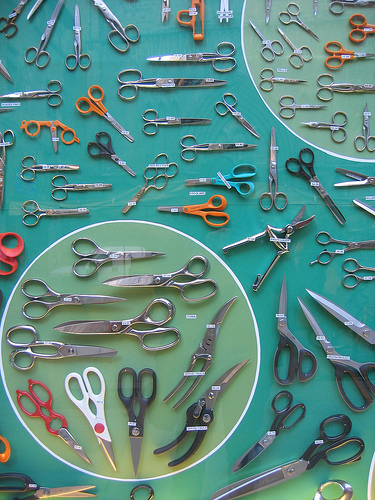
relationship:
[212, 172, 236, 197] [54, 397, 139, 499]
tag on scissors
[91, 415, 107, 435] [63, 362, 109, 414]
circle on handle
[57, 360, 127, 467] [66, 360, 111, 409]
scissors with handle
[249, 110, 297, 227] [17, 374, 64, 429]
scissors with handle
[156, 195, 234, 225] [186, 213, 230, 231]
scissors with an handles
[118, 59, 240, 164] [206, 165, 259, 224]
scissors with handles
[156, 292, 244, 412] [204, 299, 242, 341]
scissors with blade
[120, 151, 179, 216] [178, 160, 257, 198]
double scissors next to blue scissors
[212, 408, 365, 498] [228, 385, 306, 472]
large scissors next to small scissors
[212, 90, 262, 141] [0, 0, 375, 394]
scissors next to silver scissors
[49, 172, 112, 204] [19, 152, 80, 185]
scissors next to scissors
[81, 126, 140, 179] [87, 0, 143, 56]
scissor next to scissor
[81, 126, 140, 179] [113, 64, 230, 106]
scissor next to scissor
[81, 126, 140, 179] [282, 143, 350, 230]
scissor next to scissor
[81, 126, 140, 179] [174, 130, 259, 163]
scissor next to scissor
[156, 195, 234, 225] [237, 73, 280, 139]
scissors on a green surface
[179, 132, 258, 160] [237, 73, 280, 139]
scissors on a green surface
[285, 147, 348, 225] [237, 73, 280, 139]
scissors on a green surface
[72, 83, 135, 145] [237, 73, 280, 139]
scissors on a green surface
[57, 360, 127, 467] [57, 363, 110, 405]
scissors with white handles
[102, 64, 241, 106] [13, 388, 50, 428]
scissors with handle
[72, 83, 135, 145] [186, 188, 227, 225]
scissors with handles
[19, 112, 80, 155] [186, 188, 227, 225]
scissors with handles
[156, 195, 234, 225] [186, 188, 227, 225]
scissors with handles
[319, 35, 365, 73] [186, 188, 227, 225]
scissors with handles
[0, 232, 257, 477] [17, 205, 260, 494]
scissors in a circle